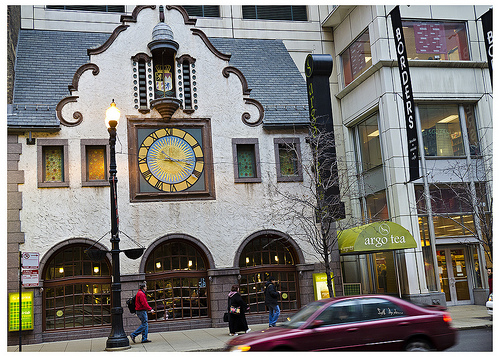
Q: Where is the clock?
A: On building.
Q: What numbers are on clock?
A: Roman numerals.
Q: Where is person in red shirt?
A: In front of clock building.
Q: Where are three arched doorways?
A: On clock building.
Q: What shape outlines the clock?
A: A square.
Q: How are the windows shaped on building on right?
A: Square.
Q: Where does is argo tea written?
A: On green awning.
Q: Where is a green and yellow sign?
A: On far left.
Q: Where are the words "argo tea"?
A: On the green arched awning.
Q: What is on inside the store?
A: Lights.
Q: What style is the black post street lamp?
A: Old fashioned.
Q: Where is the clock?
A: On the wall.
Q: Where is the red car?
A: On the road.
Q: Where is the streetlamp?
A: On the street.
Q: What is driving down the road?
A: Car.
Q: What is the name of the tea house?
A: Argo.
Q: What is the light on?
A: Pole.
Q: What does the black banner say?
A: Borders.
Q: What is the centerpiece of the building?
A: Clock.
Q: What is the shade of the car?
A: Red.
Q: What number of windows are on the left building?
A: 4.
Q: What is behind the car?
A: Tree.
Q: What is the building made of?
A: Stone.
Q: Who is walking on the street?
A: Few People.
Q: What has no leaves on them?
A: The trees.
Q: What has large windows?
A: A multi story building.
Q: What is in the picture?
A: A black banner for a business.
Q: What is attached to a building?
A: A large business sign.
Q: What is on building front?
A: A large clock.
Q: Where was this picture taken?
A: During the day.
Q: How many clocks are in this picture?
A: One.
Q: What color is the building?
A: White.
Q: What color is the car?
A: Red.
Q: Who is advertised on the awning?
A: Argo Tea.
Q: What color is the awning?
A: Green.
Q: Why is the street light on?
A: It's getting dark.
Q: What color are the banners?
A: Black.